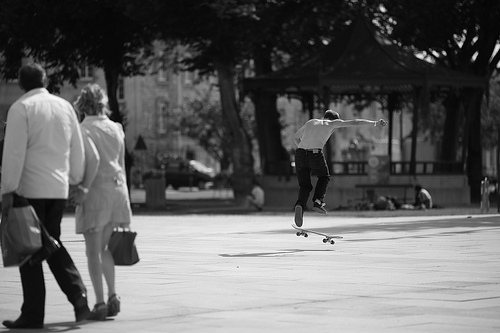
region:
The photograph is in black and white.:
[1, 44, 498, 332]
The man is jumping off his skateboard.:
[287, 109, 389, 246]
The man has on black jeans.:
[291, 148, 331, 227]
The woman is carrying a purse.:
[74, 81, 141, 322]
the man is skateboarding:
[267, 80, 349, 253]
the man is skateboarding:
[275, 78, 385, 268]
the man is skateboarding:
[257, 65, 407, 262]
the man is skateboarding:
[272, 92, 373, 265]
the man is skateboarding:
[275, 100, 348, 262]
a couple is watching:
[11, 56, 154, 320]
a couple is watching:
[6, 55, 139, 317]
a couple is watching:
[10, 50, 137, 317]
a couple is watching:
[6, 34, 188, 330]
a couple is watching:
[3, 45, 140, 325]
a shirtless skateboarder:
[291, 109, 386, 226]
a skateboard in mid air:
[287, 222, 345, 244]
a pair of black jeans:
[294, 147, 329, 214]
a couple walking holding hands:
[2, 62, 138, 329]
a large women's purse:
[107, 227, 139, 269]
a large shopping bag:
[2, 204, 40, 266]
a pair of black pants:
[14, 194, 89, 322]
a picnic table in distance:
[353, 183, 413, 207]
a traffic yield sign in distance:
[132, 133, 147, 150]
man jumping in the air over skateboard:
[280, 106, 392, 251]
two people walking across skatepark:
[1, 51, 148, 331]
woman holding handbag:
[64, 79, 146, 324]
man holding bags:
[0, 60, 101, 332]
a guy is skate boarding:
[289, 108, 385, 244]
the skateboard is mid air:
[291, 223, 343, 244]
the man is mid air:
[291, 108, 387, 228]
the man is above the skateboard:
[287, 108, 387, 245]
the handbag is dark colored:
[107, 222, 140, 264]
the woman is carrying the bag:
[71, 83, 138, 319]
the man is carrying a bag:
[1, 62, 91, 327]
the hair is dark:
[17, 62, 47, 89]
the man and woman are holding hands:
[1, 60, 132, 330]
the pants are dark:
[292, 145, 329, 209]